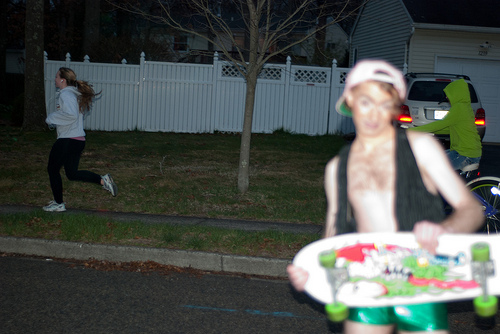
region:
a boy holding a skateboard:
[268, 55, 455, 329]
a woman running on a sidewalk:
[18, 52, 136, 213]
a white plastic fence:
[51, 57, 365, 135]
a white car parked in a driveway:
[381, 52, 478, 146]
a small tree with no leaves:
[198, 5, 297, 201]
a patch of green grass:
[7, 205, 266, 260]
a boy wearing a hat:
[310, 60, 427, 145]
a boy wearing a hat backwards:
[308, 60, 399, 143]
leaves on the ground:
[22, 244, 261, 284]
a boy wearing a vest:
[269, 44, 455, 254]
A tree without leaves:
[208, 26, 283, 196]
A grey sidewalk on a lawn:
[20, 106, 282, 267]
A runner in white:
[41, 65, 127, 230]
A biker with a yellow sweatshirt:
[425, 70, 493, 205]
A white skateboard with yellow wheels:
[283, 226, 495, 316]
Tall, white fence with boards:
[47, 50, 326, 139]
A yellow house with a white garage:
[350, 8, 495, 130]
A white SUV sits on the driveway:
[394, 56, 489, 161]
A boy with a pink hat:
[318, 54, 462, 259]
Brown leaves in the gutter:
[34, 224, 233, 296]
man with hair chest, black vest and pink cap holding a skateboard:
[287, 49, 446, 331]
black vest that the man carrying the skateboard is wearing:
[328, 124, 443, 246]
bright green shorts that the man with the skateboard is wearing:
[343, 289, 446, 330]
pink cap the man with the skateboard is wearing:
[328, 56, 406, 131]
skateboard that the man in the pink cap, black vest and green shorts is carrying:
[278, 215, 498, 316]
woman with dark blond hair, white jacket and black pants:
[31, 41, 118, 223]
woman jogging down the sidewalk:
[36, 50, 123, 229]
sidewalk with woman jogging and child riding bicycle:
[88, 202, 299, 239]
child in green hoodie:
[416, 67, 496, 245]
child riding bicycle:
[417, 72, 487, 221]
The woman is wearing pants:
[42, 131, 138, 228]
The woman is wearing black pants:
[35, 132, 126, 212]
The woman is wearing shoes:
[31, 156, 168, 219]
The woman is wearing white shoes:
[25, 161, 149, 219]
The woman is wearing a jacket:
[29, 68, 114, 173]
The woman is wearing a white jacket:
[34, 81, 116, 161]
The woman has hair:
[51, 56, 113, 118]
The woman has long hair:
[49, 50, 114, 119]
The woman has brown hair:
[50, 40, 136, 148]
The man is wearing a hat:
[321, 41, 417, 134]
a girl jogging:
[22, 66, 126, 219]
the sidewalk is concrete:
[63, 202, 311, 252]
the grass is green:
[71, 207, 295, 257]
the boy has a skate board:
[292, 52, 494, 330]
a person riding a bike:
[421, 72, 497, 226]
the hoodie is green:
[417, 65, 487, 151]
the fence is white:
[95, 65, 350, 134]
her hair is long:
[54, 67, 110, 114]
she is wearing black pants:
[34, 125, 111, 208]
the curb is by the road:
[10, 232, 291, 299]